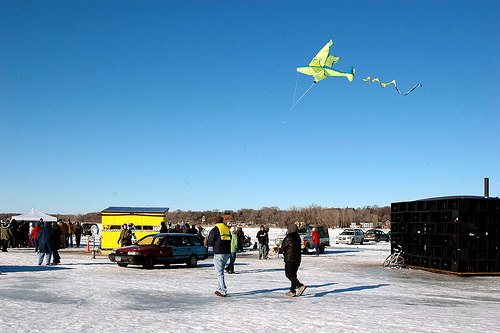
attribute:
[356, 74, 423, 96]
kite tail — thin, curly 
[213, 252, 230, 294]
trouser — faded blue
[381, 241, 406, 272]
bicycle — parked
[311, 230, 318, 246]
jacket — red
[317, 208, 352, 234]
plants — dried brown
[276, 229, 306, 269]
jackets — navy blue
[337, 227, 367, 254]
car — white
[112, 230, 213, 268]
vehicle — white, red 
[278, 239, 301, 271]
jacket — black 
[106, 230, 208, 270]
car — red, light blue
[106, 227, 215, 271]
car — maroon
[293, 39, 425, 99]
kite — light green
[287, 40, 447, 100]
kite — green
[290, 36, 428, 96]
kite —  like airplane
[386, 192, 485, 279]
box — black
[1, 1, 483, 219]
sky — clear blue